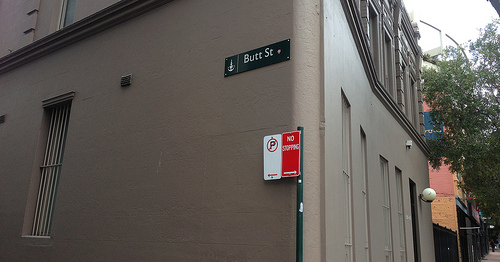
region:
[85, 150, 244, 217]
Grey exterior facade of a building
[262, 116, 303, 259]
A "No Parking/No Stopping" sign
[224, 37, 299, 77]
A green street sign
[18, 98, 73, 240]
A window with bars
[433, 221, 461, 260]
Black metal fence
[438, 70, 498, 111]
Green leaves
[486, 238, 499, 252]
Person in the distance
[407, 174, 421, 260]
Door of a building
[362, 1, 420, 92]
Several windows of a building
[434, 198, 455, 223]
Orange brick facade of a building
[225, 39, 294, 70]
black and white Butt St sign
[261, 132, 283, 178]
white red and black no parking sign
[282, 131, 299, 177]
red and white no stopping sign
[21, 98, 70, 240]
bars covering a window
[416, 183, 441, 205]
white round outside lamp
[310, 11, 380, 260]
beige concrete building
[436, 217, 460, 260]
black metal fence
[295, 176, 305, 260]
green metal sign pole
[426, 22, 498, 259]
large green tree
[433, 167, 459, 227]
peach and orange concrete building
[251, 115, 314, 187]
Red white and black sign on a wall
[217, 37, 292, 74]
Black and white street sign for Butt Street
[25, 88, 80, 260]
Tan barred window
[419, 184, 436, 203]
White light fixture on the side of a wall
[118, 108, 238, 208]
Tan wall on the outside of a building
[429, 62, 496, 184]
Green tree leaves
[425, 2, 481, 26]
Pale whit sky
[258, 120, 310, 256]
Green pole holding up a street sign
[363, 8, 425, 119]
Brick windows on the second floor of a building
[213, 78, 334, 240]
A sign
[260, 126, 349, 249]
A sign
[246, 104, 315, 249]
A sign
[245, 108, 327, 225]
a red and white no parking sign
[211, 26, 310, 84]
the sign says butt st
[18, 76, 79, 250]
bars on the windows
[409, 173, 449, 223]
a round light on the side of the building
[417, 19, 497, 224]
the leaves on the tree are green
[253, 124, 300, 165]
the P has a red circle around it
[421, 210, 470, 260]
the fence is black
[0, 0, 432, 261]
the building is tan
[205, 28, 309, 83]
the sign is black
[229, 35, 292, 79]
Butt St letters are white